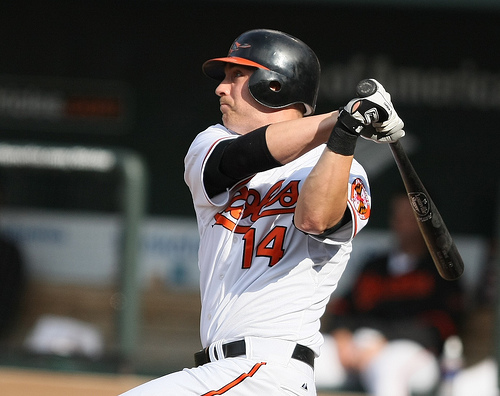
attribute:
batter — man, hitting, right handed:
[116, 28, 408, 394]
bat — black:
[356, 79, 466, 283]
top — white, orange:
[182, 123, 372, 347]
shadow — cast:
[201, 167, 373, 296]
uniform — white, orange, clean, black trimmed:
[119, 124, 372, 394]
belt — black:
[195, 339, 313, 367]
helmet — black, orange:
[202, 28, 321, 118]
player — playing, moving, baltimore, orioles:
[116, 28, 409, 393]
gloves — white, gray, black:
[327, 79, 406, 157]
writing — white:
[407, 189, 432, 222]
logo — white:
[408, 190, 430, 219]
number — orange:
[240, 225, 290, 268]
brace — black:
[204, 124, 284, 199]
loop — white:
[209, 343, 224, 362]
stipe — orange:
[200, 360, 269, 394]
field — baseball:
[4, 363, 164, 394]